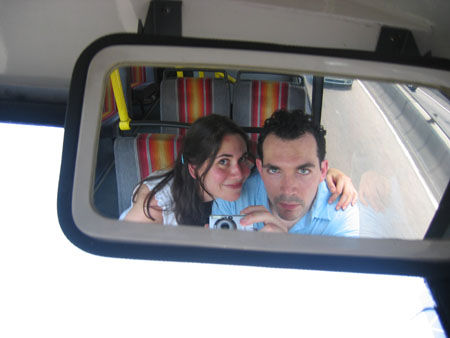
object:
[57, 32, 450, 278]
black border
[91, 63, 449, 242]
mirror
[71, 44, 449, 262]
gray border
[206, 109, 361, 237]
man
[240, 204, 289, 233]
left hand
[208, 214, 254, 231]
camera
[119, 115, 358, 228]
woman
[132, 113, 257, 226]
hair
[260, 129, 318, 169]
high forehead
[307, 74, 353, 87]
vehicle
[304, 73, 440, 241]
road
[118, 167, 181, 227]
top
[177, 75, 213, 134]
stripes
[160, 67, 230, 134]
seat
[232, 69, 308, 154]
seat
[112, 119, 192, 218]
seat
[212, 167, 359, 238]
shirt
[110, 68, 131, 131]
pole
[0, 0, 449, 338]
vehicle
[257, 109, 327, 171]
hair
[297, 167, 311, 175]
left eye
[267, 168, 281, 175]
right eye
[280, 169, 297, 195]
nose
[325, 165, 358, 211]
left hand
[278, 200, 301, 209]
mouth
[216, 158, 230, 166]
right eye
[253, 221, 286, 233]
fingers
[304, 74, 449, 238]
window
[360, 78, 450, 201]
divider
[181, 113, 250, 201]
head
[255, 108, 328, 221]
head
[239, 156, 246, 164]
eyes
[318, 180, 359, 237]
shoulder